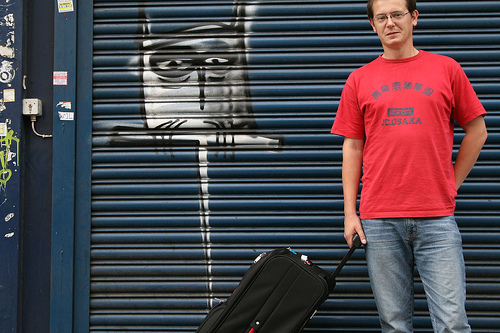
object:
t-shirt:
[330, 49, 486, 220]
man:
[329, 0, 484, 333]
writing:
[370, 81, 434, 127]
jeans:
[357, 216, 472, 333]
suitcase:
[195, 247, 336, 333]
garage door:
[92, 0, 499, 332]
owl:
[138, 1, 260, 134]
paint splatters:
[0, 128, 20, 184]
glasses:
[371, 11, 414, 22]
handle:
[331, 233, 366, 280]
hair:
[366, 0, 417, 20]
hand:
[453, 165, 458, 192]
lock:
[252, 251, 266, 266]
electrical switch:
[21, 97, 43, 116]